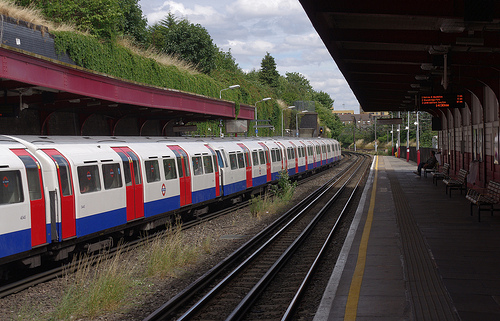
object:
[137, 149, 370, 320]
tracks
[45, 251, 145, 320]
grass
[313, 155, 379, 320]
lines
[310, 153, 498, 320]
platform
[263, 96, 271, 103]
light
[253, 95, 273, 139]
pole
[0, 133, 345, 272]
train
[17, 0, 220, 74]
trees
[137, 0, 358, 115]
clouds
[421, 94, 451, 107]
lettering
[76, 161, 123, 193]
windows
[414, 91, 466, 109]
sign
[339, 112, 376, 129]
building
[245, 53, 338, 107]
trees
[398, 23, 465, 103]
lights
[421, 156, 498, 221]
benches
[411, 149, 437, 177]
person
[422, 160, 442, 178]
bench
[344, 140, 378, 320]
line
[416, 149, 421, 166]
base of pole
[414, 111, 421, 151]
pole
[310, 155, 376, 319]
line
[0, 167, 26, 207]
window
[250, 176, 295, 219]
grass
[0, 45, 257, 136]
overhang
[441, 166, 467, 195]
bench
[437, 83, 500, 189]
wall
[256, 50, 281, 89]
tree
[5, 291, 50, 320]
stones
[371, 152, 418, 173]
sunlight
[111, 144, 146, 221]
door